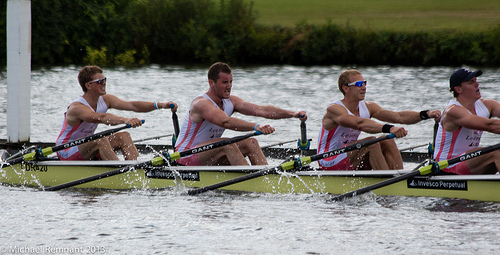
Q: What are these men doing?
A: Rowing a boat.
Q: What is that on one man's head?
A: A hat.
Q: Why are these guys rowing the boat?
A: For competition.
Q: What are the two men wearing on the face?
A: Sunglasses.